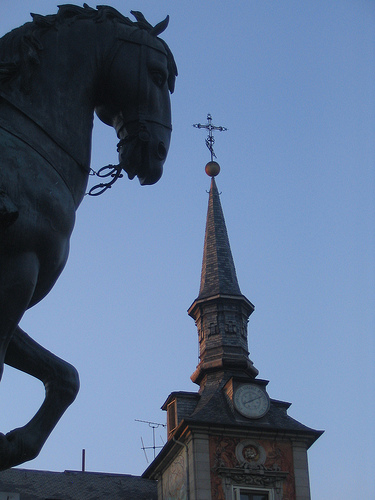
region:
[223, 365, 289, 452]
A clock is visible.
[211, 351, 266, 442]
A clock is visible.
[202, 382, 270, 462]
A clock is visible.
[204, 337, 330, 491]
A clock is visible.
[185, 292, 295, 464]
A clock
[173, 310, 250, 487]
A clock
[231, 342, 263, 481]
A clock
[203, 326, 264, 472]
A clock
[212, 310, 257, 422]
A clock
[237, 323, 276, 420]
A clock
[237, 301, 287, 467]
A clock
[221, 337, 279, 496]
A clock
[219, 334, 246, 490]
A clock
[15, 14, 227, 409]
statue of a horse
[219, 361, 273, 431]
white clock on a tower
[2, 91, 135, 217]
reigns on the horses head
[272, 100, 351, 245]
bright clear blue sky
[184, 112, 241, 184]
decorative cross all the way at the top of building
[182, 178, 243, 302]
top of building made of brick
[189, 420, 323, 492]
decorative side of building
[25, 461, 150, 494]
black shingled roof of building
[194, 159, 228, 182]
decorative gold ball beneath cross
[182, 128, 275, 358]
tower on top of building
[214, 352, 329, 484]
A clock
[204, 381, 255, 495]
A clock